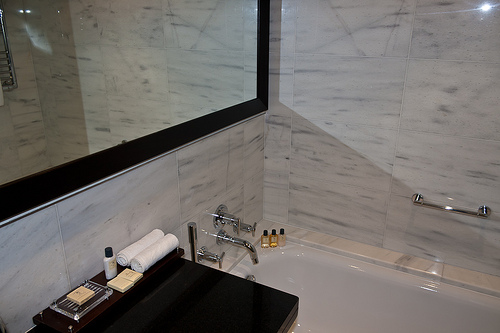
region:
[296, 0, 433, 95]
grey and white tile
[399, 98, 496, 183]
grey and white tile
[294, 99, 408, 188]
grey and white tile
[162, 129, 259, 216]
grey and white tile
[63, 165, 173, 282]
grey and white tile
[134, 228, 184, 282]
rolled up hand towel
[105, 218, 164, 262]
rolled up hand towel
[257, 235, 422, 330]
white ceramic bath tub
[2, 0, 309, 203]
rectangular mirror on wall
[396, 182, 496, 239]
silver rod by bath tub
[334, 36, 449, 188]
the walls are made of marble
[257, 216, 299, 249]
small bottles of oils set on the tub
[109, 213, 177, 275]
two towels are rolled up on the counter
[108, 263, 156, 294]
two bars of soap lay ready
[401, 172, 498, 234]
the safety bar is chrome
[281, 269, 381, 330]
the bathtub is white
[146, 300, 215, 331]
the counter is black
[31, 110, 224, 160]
the mirror is trimmed in black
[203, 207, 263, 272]
all the fixtures are chrome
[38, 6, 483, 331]
a beautiful bathroom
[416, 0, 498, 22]
the flash reflection on the wall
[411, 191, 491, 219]
the metal bar on the wall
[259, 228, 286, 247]
the bottles on the tub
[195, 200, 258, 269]
the silver water fixtures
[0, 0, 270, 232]
the mirror on the wall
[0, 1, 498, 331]
the large tiles on the bathroom walls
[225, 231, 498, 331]
the large white bath tub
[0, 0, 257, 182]
the reflection in the mirror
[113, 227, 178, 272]
the rolled white colored hand towels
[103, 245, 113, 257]
the black cap on the bottle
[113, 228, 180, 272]
the towels on the sink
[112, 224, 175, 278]
the towels are white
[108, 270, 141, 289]
the soap on the sink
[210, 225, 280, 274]
the faucet over the tub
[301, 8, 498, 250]
the tiles on the wall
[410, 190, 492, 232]
the bar on the wall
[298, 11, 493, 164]
the tiles are marble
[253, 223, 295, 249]
the soap on the tub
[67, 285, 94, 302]
the small box on the counter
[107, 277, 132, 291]
the small box on the counter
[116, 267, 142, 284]
the small box on the counter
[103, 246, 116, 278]
the small bottle on the counter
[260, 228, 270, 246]
the small bottle on the tub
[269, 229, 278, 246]
the small bottle on the tub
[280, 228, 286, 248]
the small bottle on the tub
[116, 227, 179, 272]
the rolled hand towels on the counter